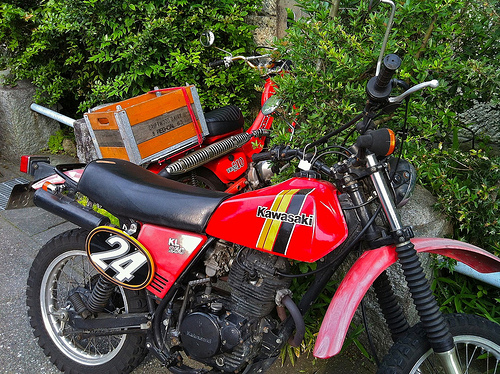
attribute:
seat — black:
[208, 104, 248, 136]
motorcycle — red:
[37, 129, 363, 359]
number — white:
[88, 232, 149, 282]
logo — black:
[81, 222, 158, 291]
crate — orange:
[79, 90, 208, 160]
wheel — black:
[375, 311, 499, 371]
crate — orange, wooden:
[81, 81, 207, 166]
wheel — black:
[21, 226, 146, 371]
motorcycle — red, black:
[14, 49, 489, 366]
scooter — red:
[21, 34, 306, 222]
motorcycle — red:
[45, 77, 490, 334]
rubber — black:
[360, 45, 407, 109]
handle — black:
[377, 51, 402, 78]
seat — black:
[75, 154, 232, 230]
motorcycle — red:
[19, 24, 491, 372]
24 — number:
[89, 235, 149, 282]